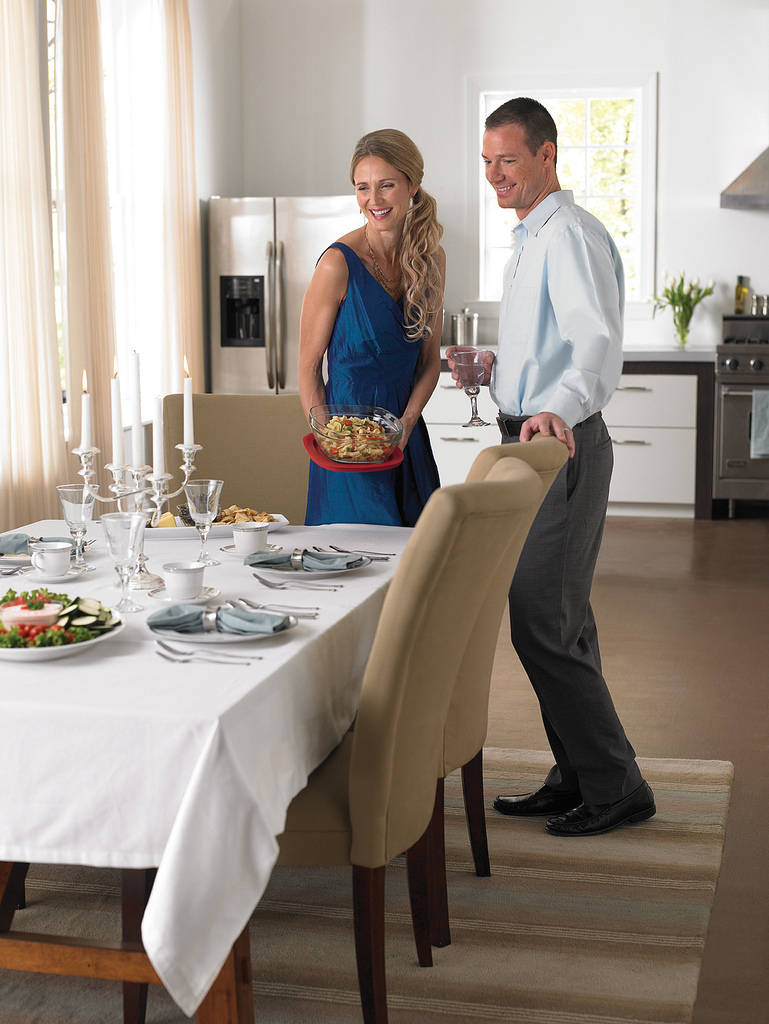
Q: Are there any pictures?
A: No, there are no pictures.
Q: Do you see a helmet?
A: No, there are no helmets.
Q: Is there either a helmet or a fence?
A: No, there are no helmets or fences.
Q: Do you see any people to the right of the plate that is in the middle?
A: Yes, there is a person to the right of the plate.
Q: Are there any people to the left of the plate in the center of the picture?
A: No, the person is to the right of the plate.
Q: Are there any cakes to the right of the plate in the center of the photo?
A: No, there is a person to the right of the plate.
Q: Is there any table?
A: Yes, there is a table.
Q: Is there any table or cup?
A: Yes, there is a table.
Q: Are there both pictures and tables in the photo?
A: No, there is a table but no pictures.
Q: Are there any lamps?
A: No, there are no lamps.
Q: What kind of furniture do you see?
A: The furniture is a table.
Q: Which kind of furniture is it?
A: The piece of furniture is a table.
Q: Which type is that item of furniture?
A: That is a table.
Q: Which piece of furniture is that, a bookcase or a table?
A: That is a table.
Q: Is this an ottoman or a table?
A: This is a table.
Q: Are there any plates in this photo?
A: Yes, there is a plate.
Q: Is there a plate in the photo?
A: Yes, there is a plate.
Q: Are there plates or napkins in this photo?
A: Yes, there is a plate.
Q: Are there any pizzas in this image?
A: No, there are no pizzas.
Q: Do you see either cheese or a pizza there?
A: No, there are no pizzas or cheese.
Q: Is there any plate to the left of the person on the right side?
A: Yes, there is a plate to the left of the person.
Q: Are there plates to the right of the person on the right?
A: No, the plate is to the left of the person.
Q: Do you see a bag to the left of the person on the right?
A: No, there is a plate to the left of the person.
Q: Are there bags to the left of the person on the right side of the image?
A: No, there is a plate to the left of the person.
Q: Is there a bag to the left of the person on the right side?
A: No, there is a plate to the left of the person.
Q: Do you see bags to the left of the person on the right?
A: No, there is a plate to the left of the person.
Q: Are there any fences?
A: No, there are no fences.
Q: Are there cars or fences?
A: No, there are no fences or cars.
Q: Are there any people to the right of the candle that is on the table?
A: Yes, there is a person to the right of the candle.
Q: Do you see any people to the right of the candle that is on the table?
A: Yes, there is a person to the right of the candle.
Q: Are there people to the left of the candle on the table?
A: No, the person is to the right of the candle.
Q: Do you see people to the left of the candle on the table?
A: No, the person is to the right of the candle.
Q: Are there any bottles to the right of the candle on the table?
A: No, there is a person to the right of the candle.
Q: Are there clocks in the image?
A: No, there are no clocks.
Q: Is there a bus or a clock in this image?
A: No, there are no clocks or buses.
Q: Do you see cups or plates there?
A: Yes, there is a plate.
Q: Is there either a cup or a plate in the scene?
A: Yes, there is a plate.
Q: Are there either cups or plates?
A: Yes, there is a plate.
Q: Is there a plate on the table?
A: Yes, there is a plate on the table.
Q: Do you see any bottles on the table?
A: No, there is a plate on the table.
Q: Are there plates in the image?
A: Yes, there is a plate.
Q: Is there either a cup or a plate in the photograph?
A: Yes, there is a plate.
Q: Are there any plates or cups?
A: Yes, there is a plate.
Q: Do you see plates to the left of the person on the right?
A: Yes, there is a plate to the left of the person.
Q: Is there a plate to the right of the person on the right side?
A: No, the plate is to the left of the person.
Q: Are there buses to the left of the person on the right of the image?
A: No, there is a plate to the left of the person.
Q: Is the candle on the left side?
A: Yes, the candle is on the left of the image.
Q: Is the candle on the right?
A: No, the candle is on the left of the image.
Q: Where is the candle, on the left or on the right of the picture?
A: The candle is on the left of the image.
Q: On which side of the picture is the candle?
A: The candle is on the left of the image.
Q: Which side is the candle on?
A: The candle is on the left of the image.